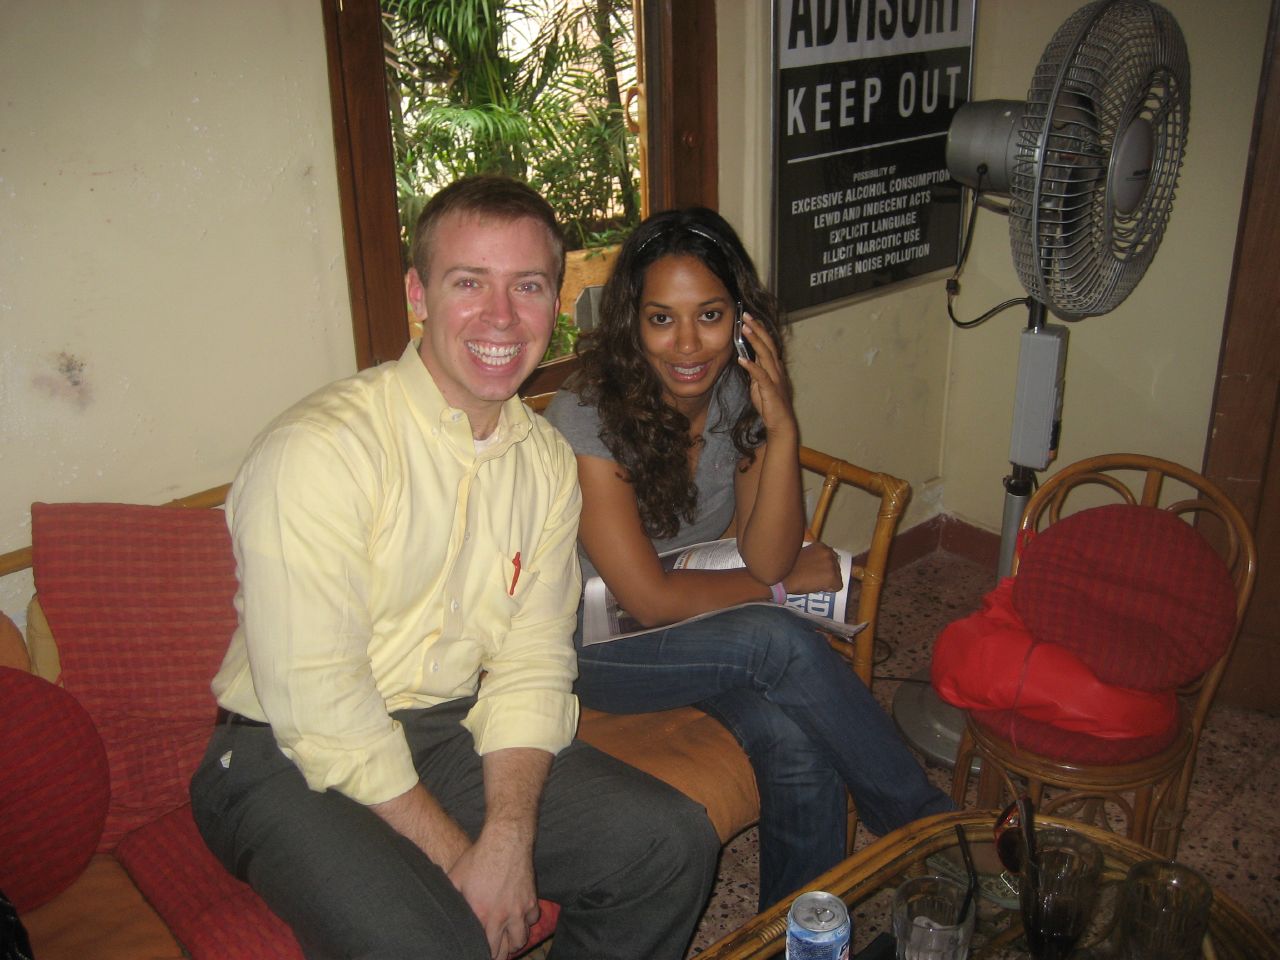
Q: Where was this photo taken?
A: In the living room.